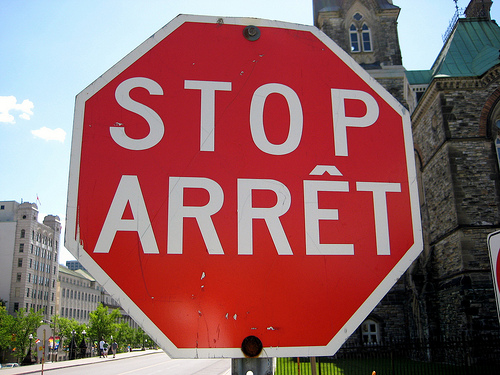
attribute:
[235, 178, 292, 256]
letter r — is white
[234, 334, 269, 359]
bolt — gray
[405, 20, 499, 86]
roof — green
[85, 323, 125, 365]
people — walking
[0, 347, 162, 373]
sidewalk — gray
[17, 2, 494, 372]
sign — big, red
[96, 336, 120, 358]
people — walking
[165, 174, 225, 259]
r — is white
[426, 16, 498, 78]
roof — green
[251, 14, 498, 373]
building. — old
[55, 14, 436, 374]
sign — octogon, octagon, red, white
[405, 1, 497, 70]
roof — green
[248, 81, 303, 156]
letter "o" — is white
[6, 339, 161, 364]
sidewalk — paved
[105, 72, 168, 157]
letter s — is white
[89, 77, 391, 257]
lettering — white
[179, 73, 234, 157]
letter t — white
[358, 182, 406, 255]
letter t — white, big